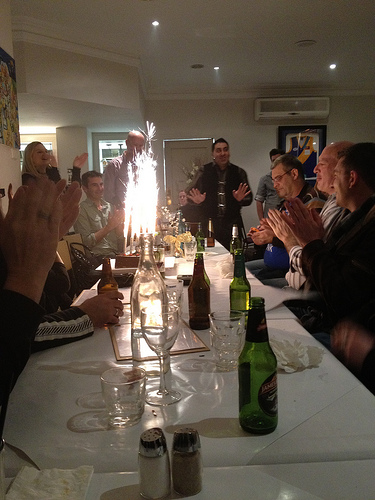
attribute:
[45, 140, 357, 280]
people — clapping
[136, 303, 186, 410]
wine glass — empty, short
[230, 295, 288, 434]
glass bottle — green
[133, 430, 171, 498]
salt shaker — here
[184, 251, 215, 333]
glass bottle — brown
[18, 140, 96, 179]
woman — clapping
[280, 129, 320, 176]
jersey — framed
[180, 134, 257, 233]
man — stadig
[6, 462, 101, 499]
napkin — square, crumpled, used